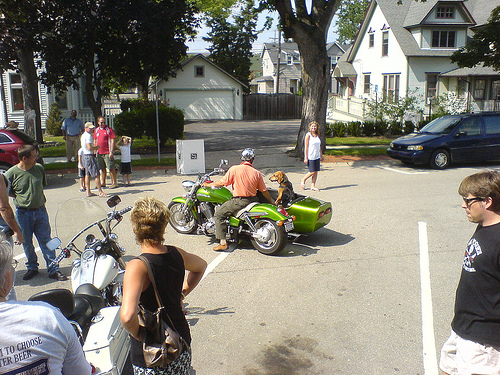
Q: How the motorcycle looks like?
A: Good.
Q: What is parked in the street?
A: Blue car.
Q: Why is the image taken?
A: Remembrance.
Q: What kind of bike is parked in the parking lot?
A: White motorcycle in lot.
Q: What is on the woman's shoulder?
A: A pocket book.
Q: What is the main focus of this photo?
A: A green motorcycle with sidecar.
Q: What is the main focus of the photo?
A: A man aside a green motorcycle.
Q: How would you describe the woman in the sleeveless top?
A: A blonde.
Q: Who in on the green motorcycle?
A: A man and dog.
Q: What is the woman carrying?
A: A brown purse.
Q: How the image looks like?
A: Busy.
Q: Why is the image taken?
A: Remembrance.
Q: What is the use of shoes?
A: Protect feet.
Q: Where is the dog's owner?
A: Driving the motorcycle.